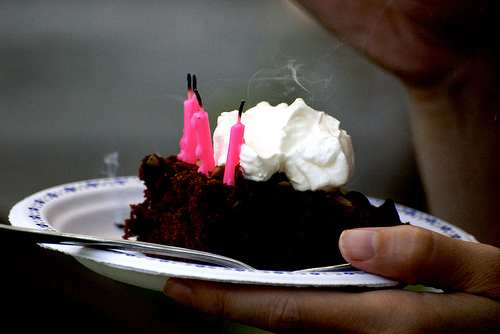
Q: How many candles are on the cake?
A: Four.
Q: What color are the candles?
A: Pink.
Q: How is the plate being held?
A: By hands.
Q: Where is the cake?
A: On the plate.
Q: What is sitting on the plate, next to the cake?
A: A fork.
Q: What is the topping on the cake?
A: Whipped cream.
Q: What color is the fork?
A: Silver.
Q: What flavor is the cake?
A: Chocolate.